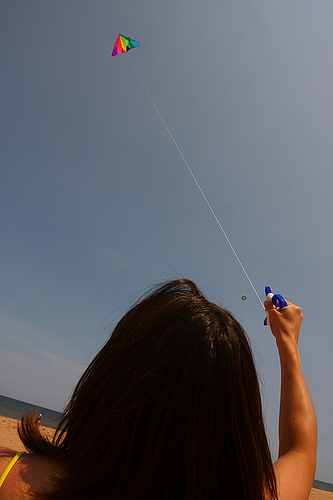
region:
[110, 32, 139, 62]
multicolored kite in the sky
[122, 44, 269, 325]
white rope holding a kite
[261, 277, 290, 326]
blue handle of kite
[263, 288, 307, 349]
right hand holding a kite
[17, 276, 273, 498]
large dark hair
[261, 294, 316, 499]
right arm of woman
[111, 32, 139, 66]
purple pink blue yellow kite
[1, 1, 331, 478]
light blue and clear sky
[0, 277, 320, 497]
woman holding a kite in the air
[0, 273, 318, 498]
woman standing on seashore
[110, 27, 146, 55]
Small kite in the sky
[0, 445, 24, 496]
Small yellow strap on womans shoulders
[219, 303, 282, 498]
Small patch of dark brown hair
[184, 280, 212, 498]
Small patch of dark brown hair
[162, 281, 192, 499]
Small patch of dark brown hair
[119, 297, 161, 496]
Small patch of dark brown hair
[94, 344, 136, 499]
Small patch of dark brown hair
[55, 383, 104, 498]
Small patch of dark brown hair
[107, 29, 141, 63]
large colored kite in the sky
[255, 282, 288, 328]
blue plastic handle with kite rope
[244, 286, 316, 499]
arm of the lady flying the kite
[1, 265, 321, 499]
lady with dark black hair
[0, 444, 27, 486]
yellow strap of a bathing suit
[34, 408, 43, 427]
person walking on the beach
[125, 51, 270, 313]
long white string of a kite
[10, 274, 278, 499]
head and hair of a woman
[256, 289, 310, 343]
hand of a lady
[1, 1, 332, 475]
sky is blue with some clouds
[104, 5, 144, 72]
A kite up the sky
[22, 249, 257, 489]
A woman flying a kite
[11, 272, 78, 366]
A blue sky surface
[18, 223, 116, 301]
A blue sky surface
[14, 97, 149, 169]
A blue sky surface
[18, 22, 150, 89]
A blue sky surface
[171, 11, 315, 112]
A blue sky surface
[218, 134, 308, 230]
A blue sky surface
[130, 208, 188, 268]
A blue sky surface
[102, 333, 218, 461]
Brown long smooth hair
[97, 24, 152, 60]
kite is multi colored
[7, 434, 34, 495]
yellow strap on woman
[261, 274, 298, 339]
string holder is blue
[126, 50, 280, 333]
string that holds the kite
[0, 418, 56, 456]
sand on the beach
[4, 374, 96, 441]
water is calm is blue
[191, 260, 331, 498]
arm is in the air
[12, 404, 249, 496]
hair is dark brown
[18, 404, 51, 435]
person on the beach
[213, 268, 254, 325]
another kite in the sky